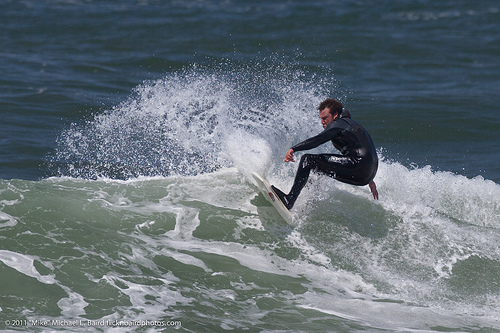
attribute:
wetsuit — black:
[273, 122, 378, 204]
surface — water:
[2, 0, 499, 331]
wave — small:
[6, 170, 499, 329]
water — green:
[35, 32, 180, 177]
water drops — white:
[152, 93, 224, 160]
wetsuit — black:
[262, 104, 396, 219]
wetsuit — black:
[251, 99, 379, 226]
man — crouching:
[274, 96, 379, 221]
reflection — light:
[302, 147, 373, 177]